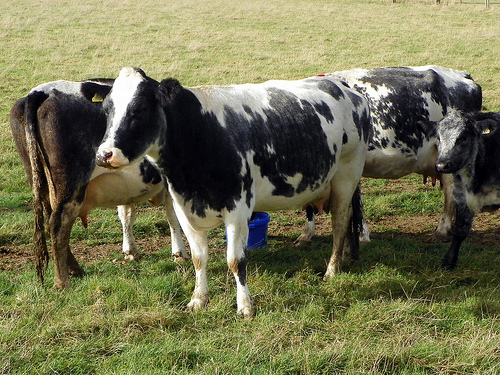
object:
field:
[10, 319, 497, 373]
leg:
[226, 205, 255, 318]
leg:
[40, 148, 88, 290]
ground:
[4, 2, 497, 373]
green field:
[0, 0, 499, 375]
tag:
[92, 93, 104, 102]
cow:
[291, 64, 482, 270]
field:
[20, 7, 465, 59]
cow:
[416, 112, 500, 270]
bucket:
[247, 211, 270, 250]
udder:
[310, 195, 331, 215]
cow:
[9, 78, 191, 290]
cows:
[80, 66, 369, 320]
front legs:
[172, 201, 210, 312]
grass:
[3, 0, 499, 375]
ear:
[155, 77, 184, 107]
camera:
[5, 54, 484, 374]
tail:
[24, 89, 48, 287]